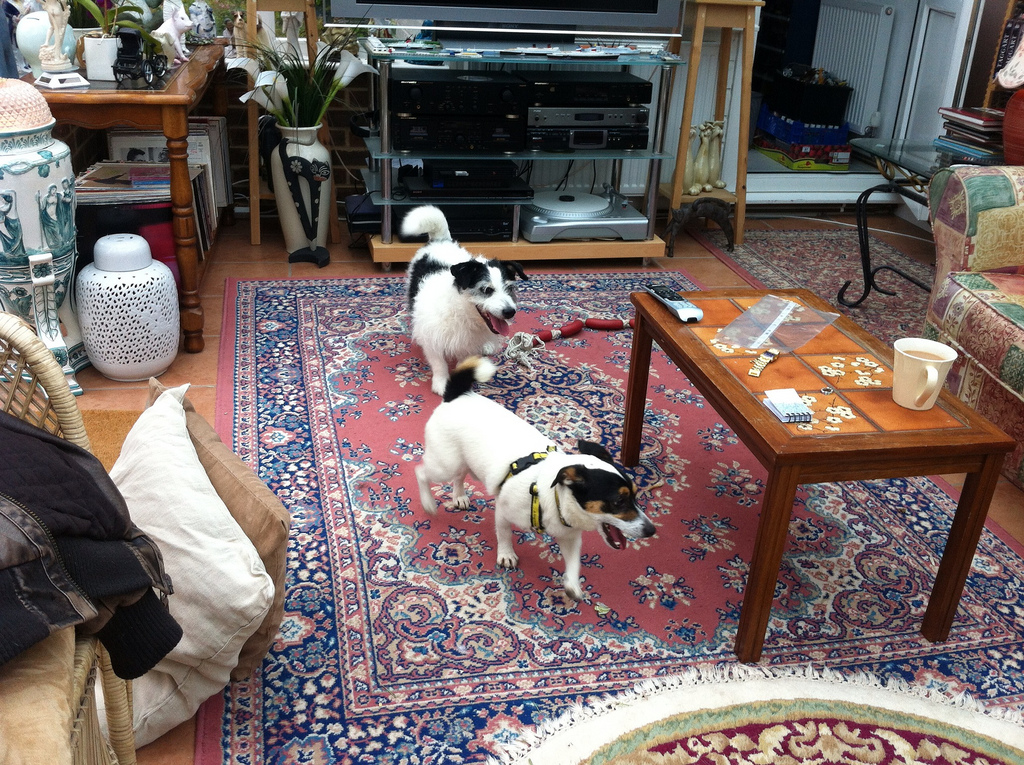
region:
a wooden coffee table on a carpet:
[627, 284, 1021, 667]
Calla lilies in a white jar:
[222, 12, 378, 266]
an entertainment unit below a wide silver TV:
[327, 0, 678, 269]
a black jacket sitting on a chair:
[0, 308, 184, 761]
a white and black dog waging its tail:
[399, 204, 530, 395]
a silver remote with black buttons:
[652, 283, 701, 325]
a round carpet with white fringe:
[497, 657, 1020, 759]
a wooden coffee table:
[618, 281, 977, 651]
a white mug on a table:
[891, 337, 949, 402]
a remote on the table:
[647, 277, 702, 326]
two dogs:
[404, 205, 660, 598]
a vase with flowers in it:
[231, 47, 362, 253]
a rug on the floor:
[195, 277, 1017, 761]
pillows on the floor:
[95, 391, 292, 747]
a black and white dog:
[394, 208, 521, 387]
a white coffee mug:
[888, 337, 952, 413]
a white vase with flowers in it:
[240, 40, 352, 253]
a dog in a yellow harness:
[424, 399, 636, 568]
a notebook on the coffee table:
[768, 380, 798, 426]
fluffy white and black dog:
[394, 200, 527, 390]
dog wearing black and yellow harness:
[416, 351, 658, 601]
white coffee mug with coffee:
[889, 331, 959, 414]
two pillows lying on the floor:
[89, 372, 295, 746]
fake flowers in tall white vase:
[188, 6, 381, 263]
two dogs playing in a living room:
[393, 203, 654, 597]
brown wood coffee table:
[620, 281, 1013, 671]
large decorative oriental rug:
[188, 268, 1021, 762]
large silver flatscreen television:
[326, 0, 693, 49]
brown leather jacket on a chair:
[1, 408, 185, 678]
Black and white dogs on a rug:
[404, 200, 660, 592]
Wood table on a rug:
[624, 275, 1018, 656]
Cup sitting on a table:
[890, 326, 960, 409]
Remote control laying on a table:
[638, 273, 706, 318]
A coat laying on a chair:
[5, 408, 187, 674]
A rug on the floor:
[208, 267, 1019, 761]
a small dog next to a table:
[412, 353, 659, 603]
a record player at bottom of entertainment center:
[517, 182, 650, 241]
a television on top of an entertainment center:
[314, 0, 685, 39]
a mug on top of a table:
[889, 334, 959, 412]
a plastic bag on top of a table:
[714, 289, 841, 354]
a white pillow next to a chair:
[92, 380, 276, 750]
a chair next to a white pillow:
[0, 305, 138, 759]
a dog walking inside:
[414, 211, 517, 401]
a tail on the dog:
[432, 351, 506, 400]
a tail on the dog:
[400, 193, 478, 286]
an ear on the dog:
[449, 261, 478, 281]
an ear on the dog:
[489, 250, 510, 285]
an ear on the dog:
[549, 445, 581, 509]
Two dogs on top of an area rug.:
[372, 194, 664, 632]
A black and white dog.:
[381, 183, 550, 430]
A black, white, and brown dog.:
[391, 361, 673, 596]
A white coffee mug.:
[887, 323, 965, 407]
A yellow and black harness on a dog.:
[476, 439, 581, 551]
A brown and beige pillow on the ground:
[100, 368, 309, 748]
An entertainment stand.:
[387, 42, 694, 271]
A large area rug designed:
[214, 254, 1020, 761]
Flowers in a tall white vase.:
[225, 8, 366, 277]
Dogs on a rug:
[353, 208, 668, 589]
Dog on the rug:
[345, 370, 659, 611]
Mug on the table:
[866, 322, 958, 420]